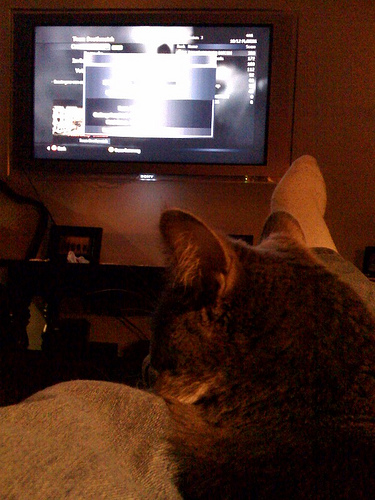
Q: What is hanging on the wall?
A: A television.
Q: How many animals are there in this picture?
A: 1.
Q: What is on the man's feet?
A: Socks.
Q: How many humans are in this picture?
A: 1.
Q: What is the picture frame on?
A: A table.